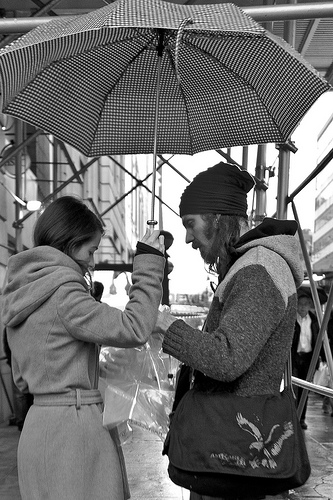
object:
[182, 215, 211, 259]
face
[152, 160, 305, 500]
man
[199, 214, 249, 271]
hair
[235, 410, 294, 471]
eagle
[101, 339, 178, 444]
bag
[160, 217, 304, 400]
hoodie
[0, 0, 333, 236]
umbrella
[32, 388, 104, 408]
belt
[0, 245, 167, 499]
coat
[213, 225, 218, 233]
earring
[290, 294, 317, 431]
man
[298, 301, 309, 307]
glasses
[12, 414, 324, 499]
tarmac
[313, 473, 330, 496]
crack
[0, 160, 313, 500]
couple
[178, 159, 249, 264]
head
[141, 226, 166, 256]
hand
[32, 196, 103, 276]
head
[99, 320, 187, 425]
plastic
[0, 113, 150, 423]
building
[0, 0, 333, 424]
construction pylon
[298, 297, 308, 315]
face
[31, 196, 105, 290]
hair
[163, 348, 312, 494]
bag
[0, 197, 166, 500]
person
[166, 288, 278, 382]
arm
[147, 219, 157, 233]
handle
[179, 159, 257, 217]
beanie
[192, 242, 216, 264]
mustache